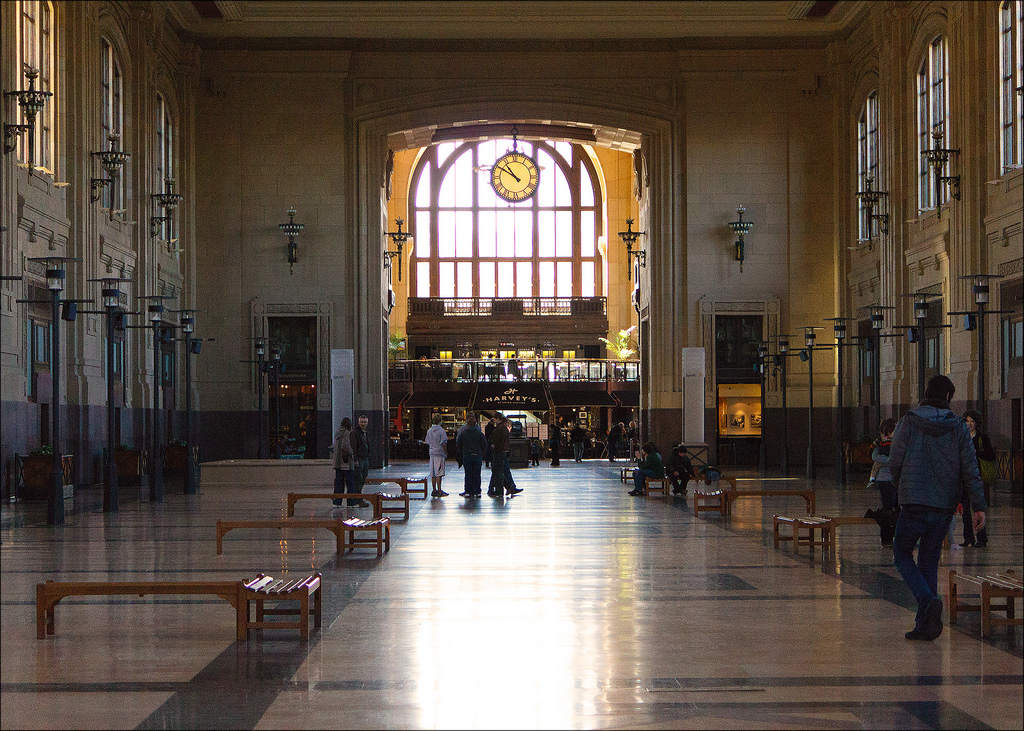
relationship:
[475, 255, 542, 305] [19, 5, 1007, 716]
window on building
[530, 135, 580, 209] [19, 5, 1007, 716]
window on building